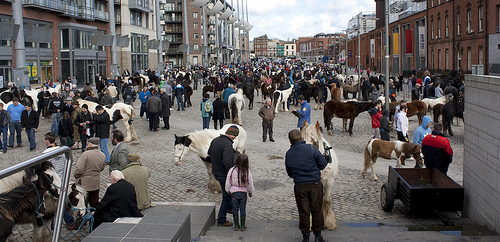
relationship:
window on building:
[184, 18, 200, 31] [157, 7, 195, 58]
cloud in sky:
[281, 6, 318, 31] [259, 8, 310, 47]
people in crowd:
[226, 38, 336, 112] [157, 31, 386, 173]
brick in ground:
[354, 194, 405, 221] [149, 132, 171, 157]